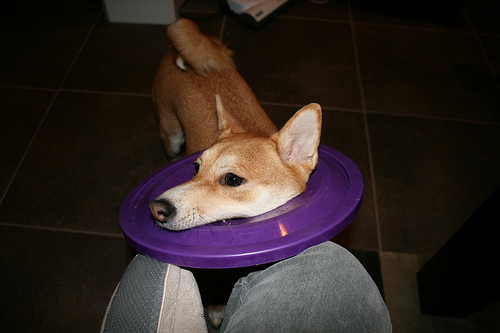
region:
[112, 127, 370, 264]
purple frisbee around the dog's head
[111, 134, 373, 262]
purple frisbee with a hole in the center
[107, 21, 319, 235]
tan colored dog with a frisbee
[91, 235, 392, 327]
person's knees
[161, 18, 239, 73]
curlty tail on the dog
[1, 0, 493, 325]
ceramic tile on the ground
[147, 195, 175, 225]
nose of the dog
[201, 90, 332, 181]
pointed ears on the dog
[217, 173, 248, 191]
left eye of the dog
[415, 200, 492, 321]
black leg of a table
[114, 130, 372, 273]
purple frisbee around dog's head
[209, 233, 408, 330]
knee of human wearing grey jeans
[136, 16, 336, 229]
blond dog with pointy ears and black eyes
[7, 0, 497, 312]
brown tiled floor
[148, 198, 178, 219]
black nose with pink tip on dog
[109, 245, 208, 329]
edge of cream and gray cushion near person's knee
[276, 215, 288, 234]
small bit of light reflected off frsibee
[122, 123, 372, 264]
round purple frisbee with inner hold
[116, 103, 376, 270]
frisbee holding dog's head in middle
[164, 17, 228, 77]
curly tail of dog reaching over rear end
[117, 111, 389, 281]
a dog sticking it's head through a frisbee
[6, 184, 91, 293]
grey stone tiles of the floor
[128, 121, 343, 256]
a purple frisbee around the dog's head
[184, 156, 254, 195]
black eyes of the dog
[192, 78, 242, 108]
brown fur of the dog's back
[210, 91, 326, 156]
the furry pointed ears of the dog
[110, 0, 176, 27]
white wall of the room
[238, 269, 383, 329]
a person's blue pant leg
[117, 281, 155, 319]
the grey sole of a person's shoe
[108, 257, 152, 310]
the shoe of the person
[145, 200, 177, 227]
the nose of the dog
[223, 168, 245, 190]
the eye of the dog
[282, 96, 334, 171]
the ear of the dog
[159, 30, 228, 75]
the tail of the dog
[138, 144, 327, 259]
the dogs head is in a frisbee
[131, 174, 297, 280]
a purple frisbee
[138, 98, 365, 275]
the face of the dog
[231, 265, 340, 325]
the jeans of the person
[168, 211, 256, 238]
the mouth of the dog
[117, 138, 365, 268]
dog wearing purple disc around neck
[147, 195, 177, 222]
nose is brown and black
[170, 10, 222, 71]
brown tail on dog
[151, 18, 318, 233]
brown dog with purple collar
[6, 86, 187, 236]
floor tile is next to floor tile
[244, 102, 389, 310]
floor tile is next to floor tile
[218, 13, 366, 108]
floor tile is next to floor tile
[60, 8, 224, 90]
floor tile is next to floor tile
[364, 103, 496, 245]
floor tile is next to floor tile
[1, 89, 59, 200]
floor tile is next to floor tile